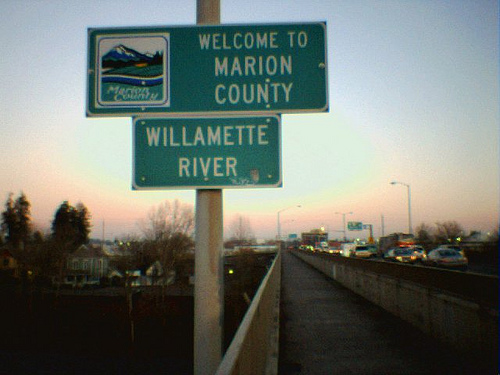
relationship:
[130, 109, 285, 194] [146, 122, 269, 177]
sign has writing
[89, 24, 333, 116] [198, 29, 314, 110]
sign has writing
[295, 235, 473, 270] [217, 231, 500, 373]
cars are on bridge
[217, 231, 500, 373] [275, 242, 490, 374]
bridge has sidewalk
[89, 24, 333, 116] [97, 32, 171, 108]
sign has picture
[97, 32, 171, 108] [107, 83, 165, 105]
picture has writing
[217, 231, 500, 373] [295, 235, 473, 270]
bridge for cars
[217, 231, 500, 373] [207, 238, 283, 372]
bridge has railing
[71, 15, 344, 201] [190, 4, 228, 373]
signs are on post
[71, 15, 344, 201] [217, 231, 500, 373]
signs are beside bridge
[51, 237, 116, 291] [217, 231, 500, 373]
house beside bridge